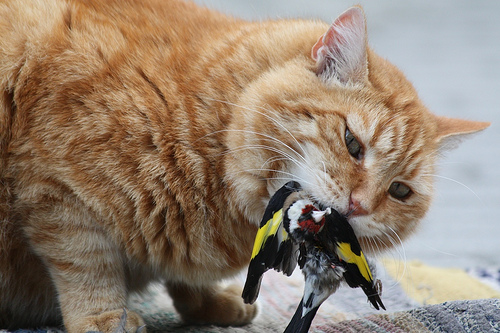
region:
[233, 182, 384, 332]
black and yellow bird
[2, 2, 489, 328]
orange and white cat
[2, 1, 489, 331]
orange cat on bench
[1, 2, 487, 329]
orange tabby cat on bench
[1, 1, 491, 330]
cat with bird in mouth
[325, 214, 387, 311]
black and yellow bird wing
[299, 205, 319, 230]
red blood on bird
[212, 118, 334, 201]
white wiskers on cat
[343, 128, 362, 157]
green eye on cat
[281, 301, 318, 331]
black tail of bird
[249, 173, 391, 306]
A dead bird in a cat's mouth.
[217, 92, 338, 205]
Several whiskers coming from the cat.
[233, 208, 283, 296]
A wing with two colors.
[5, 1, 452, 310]
A cat eating a bird.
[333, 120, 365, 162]
A single cat eye looking at the bird.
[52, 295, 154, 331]
Large cat claws on the rug.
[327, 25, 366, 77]
Hair protruding from a cat's ear.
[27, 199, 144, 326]
A fat cat leg on the ground.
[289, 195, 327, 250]
A red, white and black bird head.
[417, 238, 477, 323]
A rug on the floor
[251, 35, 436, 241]
cat is orange and white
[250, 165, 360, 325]
yellow and black bird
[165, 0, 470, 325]
cat has bird in mouth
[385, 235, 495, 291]
yellow stripe on road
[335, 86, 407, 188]
cat has green eyes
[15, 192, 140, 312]
cat has orange legs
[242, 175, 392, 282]
yellow stripe on bird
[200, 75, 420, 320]
white whiskers on bird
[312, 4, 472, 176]
cat has orange ears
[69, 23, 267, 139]
cat has orange neck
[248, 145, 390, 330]
This is a small bird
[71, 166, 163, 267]
These are two wings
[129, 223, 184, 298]
This is a cat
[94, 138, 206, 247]
The cat is striped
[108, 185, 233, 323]
This is a tabby cat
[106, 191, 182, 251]
The cat is orange and white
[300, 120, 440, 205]
The eyes are green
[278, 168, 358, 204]
These are wiskers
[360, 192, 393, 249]
This is a nose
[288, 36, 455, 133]
This is an ear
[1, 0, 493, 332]
yellow cat chewing on a bird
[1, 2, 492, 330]
fat yellow cat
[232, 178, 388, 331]
bird the yellow cat is eating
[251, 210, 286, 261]
yellow stripe on bird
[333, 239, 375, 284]
yellow stripe on bird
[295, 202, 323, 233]
red on the birds face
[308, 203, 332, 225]
birds beak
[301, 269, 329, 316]
white area on the bird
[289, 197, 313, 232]
white area on the birds face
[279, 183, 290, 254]
white area on birds wing